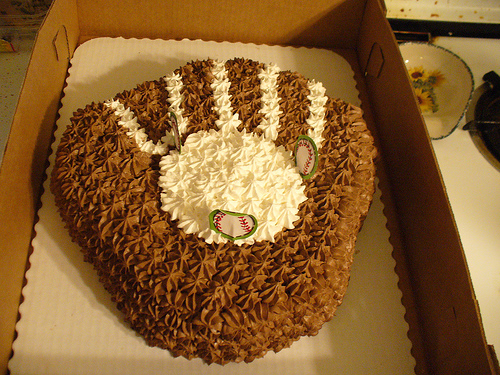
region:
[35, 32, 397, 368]
frosted cake in shape of a baseball mitt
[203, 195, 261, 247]
baseball decoration on cake frosting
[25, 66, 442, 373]
frosted cake on paper in cardboard box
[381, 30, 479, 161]
small white ceramic dish with sunflowers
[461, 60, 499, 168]
chrome stove burner with black grate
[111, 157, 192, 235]
chocolate and white frosting on cake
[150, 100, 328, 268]
three baseball decorations on mitt shaped cake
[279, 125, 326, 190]
baseball decoration with green border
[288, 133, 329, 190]
baseball decoration with red stitching detail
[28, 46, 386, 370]
cake shaped like a baseball mitt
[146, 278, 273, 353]
thick chocolate frosting on the cake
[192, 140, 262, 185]
thick white frosting on the cake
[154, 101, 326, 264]
three baseball decorations in the frosting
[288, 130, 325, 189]
baseball decoration with green border around it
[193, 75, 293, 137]
brown and white stripes of frosting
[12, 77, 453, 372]
cake on white paper in brown box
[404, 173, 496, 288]
brown box made of cardboard on counter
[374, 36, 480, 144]
small ceramic white dish with sunflowers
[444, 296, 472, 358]
cake in brown box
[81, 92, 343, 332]
cake is brown and white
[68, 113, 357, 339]
cake shaped like mitt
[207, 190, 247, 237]
baseball stickers on cake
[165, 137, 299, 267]
white circle in middle of cake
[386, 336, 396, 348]
white paper cake sits on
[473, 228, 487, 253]
cake box on stove top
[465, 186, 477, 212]
stove top is white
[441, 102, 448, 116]
tan bowl on stove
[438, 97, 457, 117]
bowl has sunflowers on it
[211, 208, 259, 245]
Baseball decoration on ball glove cake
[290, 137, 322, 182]
Baseball decoration on ball glove cake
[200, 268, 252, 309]
Part of brown icing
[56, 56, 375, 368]
Fancy ball glove cake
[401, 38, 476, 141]
Saucer with yellow daisey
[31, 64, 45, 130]
Part of brown delivery box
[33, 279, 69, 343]
Part of white sheet box covering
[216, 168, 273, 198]
Part of white icing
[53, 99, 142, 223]
Part of thumb on baseball cake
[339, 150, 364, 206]
Part of brown icing on cake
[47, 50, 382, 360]
a baseball glove cake in a box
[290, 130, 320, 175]
a base ball picture on a cake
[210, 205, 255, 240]
a base ball picture on a cake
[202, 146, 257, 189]
the white frosting of a cake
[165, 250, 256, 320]
the brown frosting of a cake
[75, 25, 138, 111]
the paper under a cake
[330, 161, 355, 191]
a star of chocolate frosting on a cake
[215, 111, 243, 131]
a star of white frosting on a cake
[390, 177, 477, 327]
the side of a box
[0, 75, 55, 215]
the side of a box